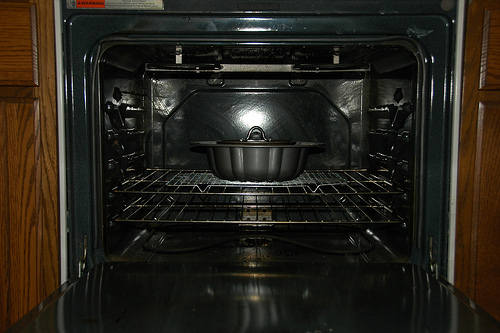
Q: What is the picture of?
A: A oven.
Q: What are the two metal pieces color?
A: Silver.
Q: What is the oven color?
A: Black.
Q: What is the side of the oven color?
A: Brown.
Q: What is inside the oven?
A: A pot.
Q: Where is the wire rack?
A: In the oven.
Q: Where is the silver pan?
A: In the oven.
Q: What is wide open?
A: The oven door.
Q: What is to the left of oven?
A: A cabinet door.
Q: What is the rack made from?
A: Metal.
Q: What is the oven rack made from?
A: Metal.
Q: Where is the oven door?
A: On the oven.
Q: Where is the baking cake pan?
A: In the stove.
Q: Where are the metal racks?
A: In the oven.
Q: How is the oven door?
A: Open.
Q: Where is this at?
A: Kitchen.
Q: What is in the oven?
A: Cake pan.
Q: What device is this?
A: Oven.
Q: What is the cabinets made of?
A: Wood.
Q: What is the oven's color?
A: Black.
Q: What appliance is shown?
A: Oven.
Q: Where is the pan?
A: In the oven.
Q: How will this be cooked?
A: Baked.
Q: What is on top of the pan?
A: A lid.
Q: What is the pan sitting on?
A: Rack.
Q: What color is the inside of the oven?
A: Black.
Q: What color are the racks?
A: Silver.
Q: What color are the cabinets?
A: Wooden.